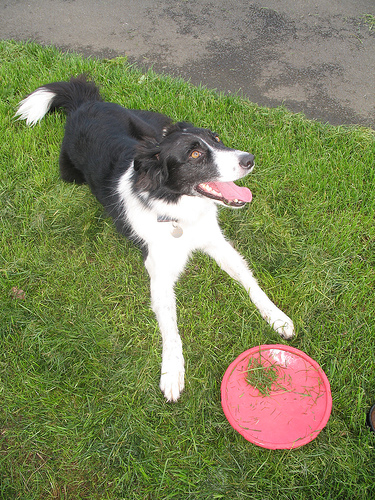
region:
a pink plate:
[218, 334, 329, 457]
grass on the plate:
[240, 358, 296, 411]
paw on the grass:
[150, 369, 194, 409]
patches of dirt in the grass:
[0, 396, 115, 498]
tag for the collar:
[164, 225, 188, 237]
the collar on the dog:
[152, 210, 175, 225]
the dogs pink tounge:
[218, 180, 254, 204]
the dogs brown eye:
[186, 145, 201, 161]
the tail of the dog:
[11, 62, 104, 125]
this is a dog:
[48, 92, 293, 299]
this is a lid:
[223, 363, 341, 434]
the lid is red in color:
[268, 412, 303, 442]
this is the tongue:
[227, 182, 251, 198]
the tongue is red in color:
[234, 186, 247, 197]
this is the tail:
[31, 80, 85, 101]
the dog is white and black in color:
[100, 171, 132, 203]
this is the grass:
[279, 137, 368, 204]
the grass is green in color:
[44, 336, 121, 416]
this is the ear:
[129, 150, 171, 183]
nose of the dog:
[229, 133, 267, 178]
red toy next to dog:
[214, 346, 343, 455]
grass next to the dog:
[61, 351, 123, 415]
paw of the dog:
[130, 314, 201, 410]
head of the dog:
[141, 127, 246, 211]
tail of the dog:
[11, 68, 101, 132]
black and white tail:
[24, 75, 94, 121]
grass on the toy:
[229, 362, 292, 406]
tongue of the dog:
[220, 181, 258, 208]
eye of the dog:
[168, 146, 211, 175]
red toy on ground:
[225, 345, 331, 441]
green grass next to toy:
[57, 405, 135, 459]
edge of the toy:
[205, 387, 251, 429]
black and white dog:
[101, 94, 264, 261]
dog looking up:
[132, 117, 262, 216]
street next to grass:
[224, 23, 308, 85]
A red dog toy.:
[209, 335, 339, 449]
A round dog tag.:
[157, 204, 200, 253]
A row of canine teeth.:
[192, 175, 253, 212]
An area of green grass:
[15, 312, 151, 478]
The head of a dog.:
[130, 115, 261, 213]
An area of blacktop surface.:
[140, 3, 354, 63]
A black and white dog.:
[9, 63, 313, 408]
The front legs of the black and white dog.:
[132, 242, 293, 404]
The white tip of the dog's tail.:
[11, 75, 62, 134]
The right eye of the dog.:
[182, 144, 214, 169]